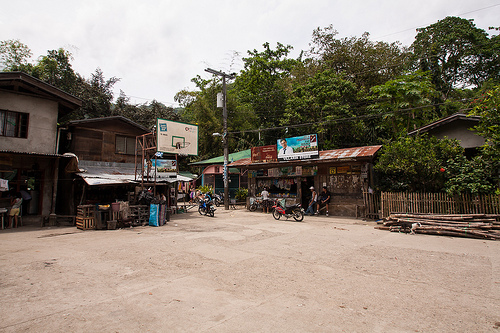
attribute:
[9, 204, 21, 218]
shorts — is yellow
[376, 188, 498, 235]
fence — Wooden 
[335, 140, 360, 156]
metal roof — is metal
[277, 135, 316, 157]
billboard — colorful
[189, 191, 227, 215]
motorcycle — small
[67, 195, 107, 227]
crates — wooden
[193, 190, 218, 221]
moped — blue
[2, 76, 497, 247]
stalls — outdoor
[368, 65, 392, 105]
ground — roof-mounted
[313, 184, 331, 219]
guy — sitting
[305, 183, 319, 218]
guy — sitting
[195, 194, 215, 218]
bike — red, black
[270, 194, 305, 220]
motorcycle — red, black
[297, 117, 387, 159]
roof — green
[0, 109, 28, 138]
window — small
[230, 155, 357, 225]
shacks — small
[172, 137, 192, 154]
basketball hoop — homemade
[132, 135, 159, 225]
hoop stand — rusted pipe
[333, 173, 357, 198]
wall — cement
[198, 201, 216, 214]
bicycle — blue